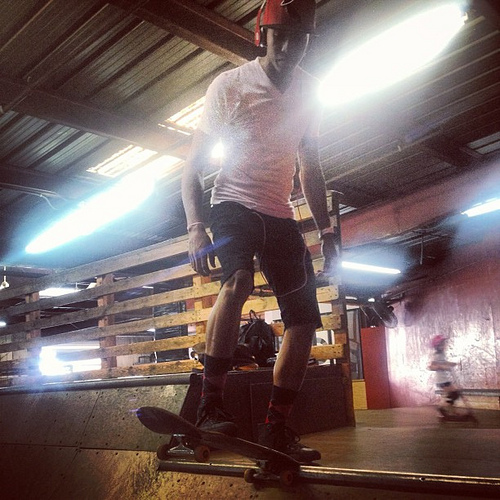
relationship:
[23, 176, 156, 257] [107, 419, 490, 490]
light on ramp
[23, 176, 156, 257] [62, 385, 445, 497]
light on ramp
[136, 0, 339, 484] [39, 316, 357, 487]
man on ramp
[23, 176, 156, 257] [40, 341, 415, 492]
light on ramp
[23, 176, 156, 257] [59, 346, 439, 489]
light on ramp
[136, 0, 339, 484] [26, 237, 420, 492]
man on ramp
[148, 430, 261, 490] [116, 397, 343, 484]
wheels on skateboard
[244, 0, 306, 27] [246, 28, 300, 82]
helmet on head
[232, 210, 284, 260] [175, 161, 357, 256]
cord on waist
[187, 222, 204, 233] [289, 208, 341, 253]
band on wrist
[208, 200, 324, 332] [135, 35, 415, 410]
short on man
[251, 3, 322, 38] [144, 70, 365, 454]
hat on person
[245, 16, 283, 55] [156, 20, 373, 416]
headphones on person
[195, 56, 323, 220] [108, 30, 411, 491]
shirt on person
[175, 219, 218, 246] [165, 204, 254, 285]
band on wrist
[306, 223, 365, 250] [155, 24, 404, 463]
watch on person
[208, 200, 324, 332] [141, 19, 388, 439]
short on person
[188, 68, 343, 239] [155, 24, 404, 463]
shirt on person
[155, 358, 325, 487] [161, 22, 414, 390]
socks on person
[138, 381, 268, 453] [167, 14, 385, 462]
shoes on person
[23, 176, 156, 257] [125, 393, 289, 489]
light on skateboard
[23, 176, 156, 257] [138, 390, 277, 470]
light on skateboard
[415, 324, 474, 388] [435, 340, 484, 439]
child on scooter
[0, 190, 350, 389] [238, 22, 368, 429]
fence behind man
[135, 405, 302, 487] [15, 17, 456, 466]
board in a building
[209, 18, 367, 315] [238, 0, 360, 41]
man wearing helmet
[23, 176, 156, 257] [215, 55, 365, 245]
light wearing shirt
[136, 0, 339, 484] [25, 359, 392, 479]
man on ramp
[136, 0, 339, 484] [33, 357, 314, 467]
man on ramp